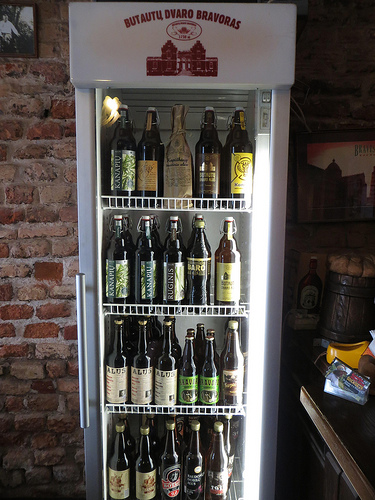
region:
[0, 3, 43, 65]
small photo on wall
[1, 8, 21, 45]
man sitting in photo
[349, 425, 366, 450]
top of counter top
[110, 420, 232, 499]
bottles on bottom shelf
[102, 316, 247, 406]
bottles on third shelf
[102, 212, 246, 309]
bottles on second shelf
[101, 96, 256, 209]
bottle of top shelf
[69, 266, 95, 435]
silver handle on door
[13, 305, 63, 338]
wall made of red brick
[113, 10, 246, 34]
red lettering on top of fridge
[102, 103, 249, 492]
the bottles in the fridge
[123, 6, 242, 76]
the writing on the top of the fridge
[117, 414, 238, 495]
the bottles on the bottom shelf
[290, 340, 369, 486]
a counter next to the fridge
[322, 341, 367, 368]
a little yellow decoration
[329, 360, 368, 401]
some business cards sitting in a container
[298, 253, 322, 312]
a box next to the wall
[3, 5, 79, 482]
the brick wall by the fridge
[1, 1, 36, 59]
the picture on the wall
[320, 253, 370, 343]
a wooden decoration on the counter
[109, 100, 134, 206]
a fancy bottle of beer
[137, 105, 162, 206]
a fancy bottle of beer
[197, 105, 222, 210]
a fancy bottle of beer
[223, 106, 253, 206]
a fancy bottle of beer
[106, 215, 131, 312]
a fancy bottle of beer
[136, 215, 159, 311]
a fancy bottle of beer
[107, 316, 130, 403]
a fancy bottle of beer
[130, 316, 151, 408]
a fancy bottle of beer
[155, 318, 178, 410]
a fancy bottle of beer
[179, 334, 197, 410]
a fancy bottle of beer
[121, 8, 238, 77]
brand name is written in red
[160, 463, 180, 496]
black and red label on the bottle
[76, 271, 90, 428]
metal door handle on the refrigerator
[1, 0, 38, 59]
artwork on the wall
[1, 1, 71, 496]
red brick wall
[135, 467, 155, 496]
tall bottle label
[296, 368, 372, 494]
wooden counter top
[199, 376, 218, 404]
green bottle label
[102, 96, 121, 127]
light reflection on the glass door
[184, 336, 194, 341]
a bottle cap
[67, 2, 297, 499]
a large beer cooler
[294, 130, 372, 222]
advertisement sign on wall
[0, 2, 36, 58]
black and white framed photograph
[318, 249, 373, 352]
cushoned topped wooden barrel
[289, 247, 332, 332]
a wooden case of liqour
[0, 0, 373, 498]
large bricked wall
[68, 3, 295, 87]
a painted advertisement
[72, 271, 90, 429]
large elongated cooler handle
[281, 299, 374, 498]
a wooden bar top